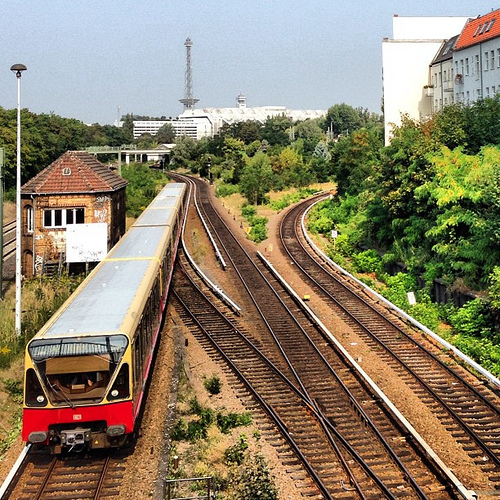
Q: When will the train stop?
A: When it reaches the train station.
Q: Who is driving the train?
A: A conductor.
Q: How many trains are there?
A: One.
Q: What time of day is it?
A: Daytime.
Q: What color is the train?
A: Red and yellow.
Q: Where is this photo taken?
A: Outside on a railroad.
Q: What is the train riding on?
A: Railroad tracks.